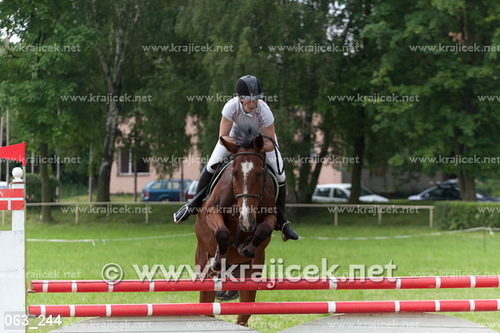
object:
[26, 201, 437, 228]
background fence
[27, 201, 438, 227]
wooden rail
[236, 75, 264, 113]
head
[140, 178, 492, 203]
cars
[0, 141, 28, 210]
flag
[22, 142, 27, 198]
pole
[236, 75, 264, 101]
helmet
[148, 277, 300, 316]
poles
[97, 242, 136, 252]
grass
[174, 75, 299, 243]
jockey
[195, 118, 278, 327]
horse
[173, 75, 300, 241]
person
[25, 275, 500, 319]
gate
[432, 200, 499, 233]
bushes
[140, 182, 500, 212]
street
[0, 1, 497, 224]
trees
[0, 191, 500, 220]
street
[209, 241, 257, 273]
hooves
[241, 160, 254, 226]
stripe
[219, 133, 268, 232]
head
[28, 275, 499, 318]
jumping rails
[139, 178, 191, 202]
car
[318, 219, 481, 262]
grass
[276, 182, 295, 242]
boot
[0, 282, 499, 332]
wall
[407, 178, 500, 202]
car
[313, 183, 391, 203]
car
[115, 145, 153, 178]
window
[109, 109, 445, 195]
building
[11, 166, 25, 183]
knob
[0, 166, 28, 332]
fence post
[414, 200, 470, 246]
garden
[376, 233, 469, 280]
grass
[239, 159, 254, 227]
fur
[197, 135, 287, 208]
pants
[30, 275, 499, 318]
obstacle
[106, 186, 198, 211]
street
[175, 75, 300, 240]
rider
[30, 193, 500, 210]
road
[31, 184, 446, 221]
field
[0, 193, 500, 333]
ground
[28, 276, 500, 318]
marks